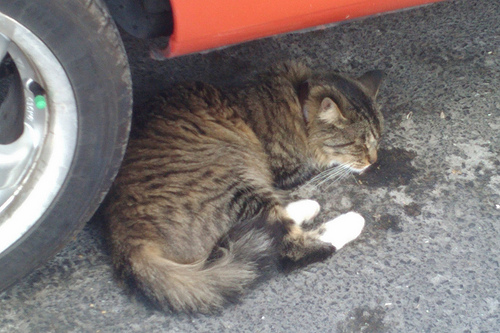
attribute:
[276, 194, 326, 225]
feet — white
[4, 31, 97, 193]
wheel cap — green 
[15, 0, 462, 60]
car — red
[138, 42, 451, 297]
cat — brown, black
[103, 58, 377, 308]
cat —  black, brown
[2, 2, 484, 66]
car — red, metal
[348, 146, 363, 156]
eyes — closed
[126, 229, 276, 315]
tail — tan, brown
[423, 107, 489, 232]
cement — white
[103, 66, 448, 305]
cat — tired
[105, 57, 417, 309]
cat — furry, brown,  black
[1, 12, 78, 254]
rim — metal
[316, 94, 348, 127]
ear — pointed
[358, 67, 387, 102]
ear — pointed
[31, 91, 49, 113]
nozzle cover — green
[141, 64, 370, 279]
cat — brown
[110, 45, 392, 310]
cat — brown 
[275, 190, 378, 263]
feet — white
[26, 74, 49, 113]
air cap — green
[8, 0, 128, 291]
tire — black, rubber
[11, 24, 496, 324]
concrete — messy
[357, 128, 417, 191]
spot — oil